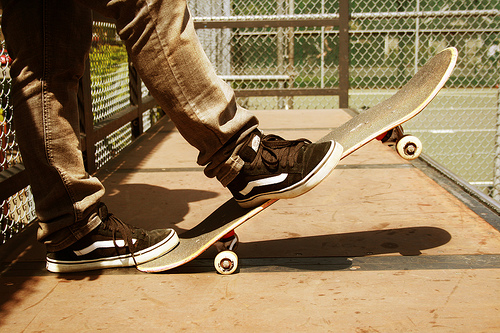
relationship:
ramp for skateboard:
[4, 102, 499, 328] [131, 44, 461, 276]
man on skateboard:
[0, 1, 346, 314] [131, 44, 461, 276]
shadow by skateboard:
[156, 221, 451, 271] [131, 44, 461, 276]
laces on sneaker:
[250, 134, 313, 171] [229, 131, 338, 211]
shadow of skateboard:
[156, 221, 451, 271] [131, 44, 461, 276]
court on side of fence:
[269, 87, 499, 180] [188, 1, 498, 127]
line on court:
[402, 124, 499, 137] [269, 87, 499, 180]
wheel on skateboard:
[392, 134, 424, 161] [131, 44, 461, 276]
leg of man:
[105, 2, 329, 185] [0, 1, 346, 314]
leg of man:
[1, 0, 183, 271] [0, 1, 346, 314]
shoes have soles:
[38, 130, 346, 281] [46, 230, 177, 273]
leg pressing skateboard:
[105, 2, 329, 185] [131, 44, 461, 276]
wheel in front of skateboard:
[392, 134, 424, 161] [131, 44, 461, 276]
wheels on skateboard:
[211, 230, 244, 277] [131, 44, 461, 276]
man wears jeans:
[0, 1, 346, 314] [1, 2, 261, 251]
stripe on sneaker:
[235, 174, 286, 196] [229, 131, 338, 211]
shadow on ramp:
[156, 221, 451, 271] [4, 102, 499, 328]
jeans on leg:
[1, 2, 261, 251] [105, 2, 329, 185]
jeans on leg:
[1, 2, 261, 251] [1, 0, 183, 271]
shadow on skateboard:
[180, 195, 249, 239] [131, 44, 461, 276]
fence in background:
[188, 1, 498, 127] [208, 53, 494, 55]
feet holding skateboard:
[42, 126, 349, 277] [131, 44, 461, 276]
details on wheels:
[224, 231, 233, 244] [211, 230, 244, 277]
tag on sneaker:
[247, 133, 263, 153] [229, 131, 338, 211]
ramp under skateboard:
[4, 102, 499, 328] [131, 44, 461, 276]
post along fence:
[186, 7, 499, 21] [188, 1, 498, 127]